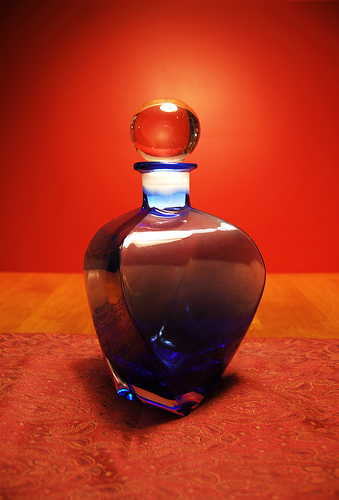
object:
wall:
[1, 1, 337, 272]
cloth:
[2, 328, 337, 494]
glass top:
[126, 96, 201, 158]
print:
[55, 410, 95, 448]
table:
[1, 270, 338, 498]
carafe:
[81, 158, 268, 415]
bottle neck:
[135, 168, 196, 210]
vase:
[83, 97, 269, 412]